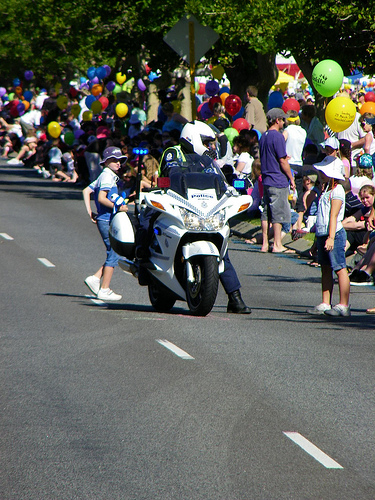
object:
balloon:
[311, 58, 343, 99]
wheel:
[185, 238, 220, 317]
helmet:
[180, 120, 216, 157]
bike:
[108, 190, 252, 316]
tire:
[148, 276, 175, 305]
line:
[155, 337, 195, 359]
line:
[91, 294, 104, 304]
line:
[36, 256, 55, 266]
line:
[0, 232, 13, 240]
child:
[306, 153, 356, 319]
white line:
[282, 428, 345, 469]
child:
[82, 147, 129, 302]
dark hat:
[97, 146, 128, 164]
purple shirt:
[257, 127, 291, 190]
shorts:
[260, 182, 291, 223]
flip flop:
[270, 246, 297, 253]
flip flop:
[260, 247, 271, 252]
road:
[0, 154, 373, 497]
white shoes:
[97, 286, 122, 300]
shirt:
[88, 167, 120, 221]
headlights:
[177, 205, 230, 233]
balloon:
[324, 95, 357, 132]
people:
[0, 60, 148, 183]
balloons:
[356, 101, 375, 114]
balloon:
[104, 79, 114, 91]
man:
[258, 106, 297, 253]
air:
[248, 26, 363, 161]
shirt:
[314, 182, 345, 237]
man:
[156, 120, 253, 315]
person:
[50, 140, 64, 182]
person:
[86, 135, 100, 148]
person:
[139, 132, 148, 144]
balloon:
[47, 119, 61, 138]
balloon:
[116, 68, 126, 85]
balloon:
[114, 101, 127, 119]